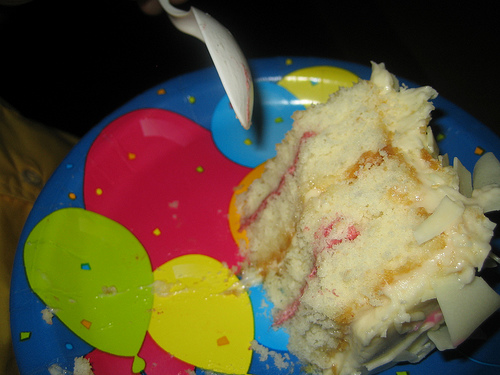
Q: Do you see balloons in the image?
A: Yes, there is a balloon.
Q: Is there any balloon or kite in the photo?
A: Yes, there is a balloon.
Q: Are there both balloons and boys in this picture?
A: No, there is a balloon but no boys.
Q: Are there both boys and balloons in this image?
A: No, there is a balloon but no boys.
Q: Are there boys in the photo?
A: No, there are no boys.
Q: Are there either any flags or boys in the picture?
A: No, there are no boys or flags.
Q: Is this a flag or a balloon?
A: This is a balloon.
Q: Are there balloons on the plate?
A: Yes, there is a balloon on the plate.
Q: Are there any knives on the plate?
A: No, there is a balloon on the plate.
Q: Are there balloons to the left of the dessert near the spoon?
A: Yes, there is a balloon to the left of the cake.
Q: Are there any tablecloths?
A: No, there are no tablecloths.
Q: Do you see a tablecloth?
A: No, there are no tablecloths.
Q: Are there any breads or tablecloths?
A: No, there are no tablecloths or breads.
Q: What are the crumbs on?
A: The crumbs are on the plate.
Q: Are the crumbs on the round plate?
A: Yes, the crumbs are on the plate.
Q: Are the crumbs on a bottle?
A: No, the crumbs are on the plate.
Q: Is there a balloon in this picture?
A: Yes, there is a balloon.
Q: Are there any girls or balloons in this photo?
A: Yes, there is a balloon.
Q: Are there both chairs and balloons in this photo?
A: No, there is a balloon but no chairs.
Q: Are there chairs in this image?
A: No, there are no chairs.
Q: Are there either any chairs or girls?
A: No, there are no chairs or girls.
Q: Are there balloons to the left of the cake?
A: Yes, there is a balloon to the left of the cake.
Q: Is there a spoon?
A: Yes, there is a spoon.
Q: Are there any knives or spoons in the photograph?
A: Yes, there is a spoon.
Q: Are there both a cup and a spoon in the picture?
A: No, there is a spoon but no cups.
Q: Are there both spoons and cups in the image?
A: No, there is a spoon but no cups.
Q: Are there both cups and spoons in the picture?
A: No, there is a spoon but no cups.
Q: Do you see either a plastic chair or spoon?
A: Yes, there is a plastic spoon.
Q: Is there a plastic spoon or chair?
A: Yes, there is a plastic spoon.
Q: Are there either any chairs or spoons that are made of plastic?
A: Yes, the spoon is made of plastic.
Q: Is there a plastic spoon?
A: Yes, there is a spoon that is made of plastic.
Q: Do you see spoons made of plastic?
A: Yes, there is a spoon that is made of plastic.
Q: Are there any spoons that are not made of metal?
A: Yes, there is a spoon that is made of plastic.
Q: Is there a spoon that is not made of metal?
A: Yes, there is a spoon that is made of plastic.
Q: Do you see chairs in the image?
A: No, there are no chairs.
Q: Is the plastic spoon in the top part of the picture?
A: Yes, the spoon is in the top of the image.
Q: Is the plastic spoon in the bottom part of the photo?
A: No, the spoon is in the top of the image.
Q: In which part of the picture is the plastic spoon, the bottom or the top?
A: The spoon is in the top of the image.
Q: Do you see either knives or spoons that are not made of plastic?
A: No, there is a spoon but it is made of plastic.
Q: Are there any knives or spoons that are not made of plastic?
A: No, there is a spoon but it is made of plastic.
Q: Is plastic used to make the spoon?
A: Yes, the spoon is made of plastic.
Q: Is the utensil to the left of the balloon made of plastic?
A: Yes, the spoon is made of plastic.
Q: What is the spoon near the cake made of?
A: The spoon is made of plastic.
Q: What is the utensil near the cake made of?
A: The spoon is made of plastic.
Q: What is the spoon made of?
A: The spoon is made of plastic.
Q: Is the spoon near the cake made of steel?
A: No, the spoon is made of plastic.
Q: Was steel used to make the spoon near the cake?
A: No, the spoon is made of plastic.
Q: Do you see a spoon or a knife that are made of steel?
A: No, there is a spoon but it is made of plastic.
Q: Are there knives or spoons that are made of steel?
A: No, there is a spoon but it is made of plastic.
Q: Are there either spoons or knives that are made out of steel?
A: No, there is a spoon but it is made of plastic.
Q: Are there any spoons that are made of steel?
A: No, there is a spoon but it is made of plastic.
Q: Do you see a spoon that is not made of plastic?
A: No, there is a spoon but it is made of plastic.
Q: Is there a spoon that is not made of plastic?
A: No, there is a spoon but it is made of plastic.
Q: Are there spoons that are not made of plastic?
A: No, there is a spoon but it is made of plastic.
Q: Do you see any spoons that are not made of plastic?
A: No, there is a spoon but it is made of plastic.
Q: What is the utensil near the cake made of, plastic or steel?
A: The spoon is made of plastic.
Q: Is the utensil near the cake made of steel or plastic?
A: The spoon is made of plastic.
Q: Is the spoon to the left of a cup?
A: No, the spoon is to the left of the balloon.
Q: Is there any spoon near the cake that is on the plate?
A: Yes, there is a spoon near the cake.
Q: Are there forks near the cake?
A: No, there is a spoon near the cake.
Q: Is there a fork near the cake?
A: No, there is a spoon near the cake.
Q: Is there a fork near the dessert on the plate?
A: No, there is a spoon near the cake.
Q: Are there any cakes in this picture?
A: Yes, there is a cake.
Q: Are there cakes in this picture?
A: Yes, there is a cake.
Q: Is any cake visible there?
A: Yes, there is a cake.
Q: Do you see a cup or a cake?
A: Yes, there is a cake.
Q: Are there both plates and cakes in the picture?
A: Yes, there are both a cake and a plate.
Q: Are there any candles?
A: No, there are no candles.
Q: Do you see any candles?
A: No, there are no candles.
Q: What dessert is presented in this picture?
A: The dessert is a cake.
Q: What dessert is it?
A: The dessert is a cake.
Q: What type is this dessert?
A: This is a cake.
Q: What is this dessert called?
A: This is a cake.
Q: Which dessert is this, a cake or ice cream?
A: This is a cake.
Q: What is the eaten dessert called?
A: The dessert is a cake.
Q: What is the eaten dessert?
A: The dessert is a cake.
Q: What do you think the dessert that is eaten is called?
A: The dessert is a cake.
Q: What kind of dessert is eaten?
A: The dessert is a cake.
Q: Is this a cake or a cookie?
A: This is a cake.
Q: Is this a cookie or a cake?
A: This is a cake.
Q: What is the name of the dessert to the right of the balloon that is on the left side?
A: The dessert is a cake.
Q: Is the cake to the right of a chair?
A: No, the cake is to the right of the balloon.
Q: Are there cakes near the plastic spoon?
A: Yes, there is a cake near the spoon.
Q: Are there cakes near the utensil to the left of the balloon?
A: Yes, there is a cake near the spoon.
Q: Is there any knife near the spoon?
A: No, there is a cake near the spoon.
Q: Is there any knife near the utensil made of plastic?
A: No, there is a cake near the spoon.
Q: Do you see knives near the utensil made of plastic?
A: No, there is a cake near the spoon.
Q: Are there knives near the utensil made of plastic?
A: No, there is a cake near the spoon.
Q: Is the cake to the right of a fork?
A: No, the cake is to the right of the balloon.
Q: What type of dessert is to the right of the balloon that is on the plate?
A: The dessert is a cake.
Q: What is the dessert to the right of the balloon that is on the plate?
A: The dessert is a cake.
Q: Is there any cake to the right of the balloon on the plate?
A: Yes, there is a cake to the right of the balloon.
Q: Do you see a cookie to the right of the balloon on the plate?
A: No, there is a cake to the right of the balloon.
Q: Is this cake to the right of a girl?
A: No, the cake is to the right of the balloon.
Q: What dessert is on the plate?
A: The dessert is a cake.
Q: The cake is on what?
A: The cake is on the plate.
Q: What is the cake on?
A: The cake is on the plate.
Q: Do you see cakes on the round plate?
A: Yes, there is a cake on the plate.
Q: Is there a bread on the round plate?
A: No, there is a cake on the plate.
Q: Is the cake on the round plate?
A: Yes, the cake is on the plate.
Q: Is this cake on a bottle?
A: No, the cake is on the plate.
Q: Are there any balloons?
A: Yes, there is a balloon.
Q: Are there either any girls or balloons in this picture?
A: Yes, there is a balloon.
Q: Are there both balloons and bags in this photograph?
A: No, there is a balloon but no bags.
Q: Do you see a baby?
A: No, there are no babies.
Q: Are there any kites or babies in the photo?
A: No, there are no babies or kites.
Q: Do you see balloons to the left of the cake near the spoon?
A: Yes, there is a balloon to the left of the cake.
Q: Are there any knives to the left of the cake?
A: No, there is a balloon to the left of the cake.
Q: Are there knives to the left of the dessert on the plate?
A: No, there is a balloon to the left of the cake.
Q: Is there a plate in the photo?
A: Yes, there is a plate.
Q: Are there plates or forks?
A: Yes, there is a plate.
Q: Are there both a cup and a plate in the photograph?
A: No, there is a plate but no cups.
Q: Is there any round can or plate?
A: Yes, there is a round plate.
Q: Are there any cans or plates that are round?
A: Yes, the plate is round.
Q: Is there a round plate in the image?
A: Yes, there is a round plate.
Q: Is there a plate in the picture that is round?
A: Yes, there is a plate that is round.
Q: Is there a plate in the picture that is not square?
A: Yes, there is a round plate.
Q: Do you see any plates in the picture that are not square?
A: Yes, there is a round plate.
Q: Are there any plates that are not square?
A: Yes, there is a round plate.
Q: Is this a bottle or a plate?
A: This is a plate.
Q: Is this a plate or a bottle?
A: This is a plate.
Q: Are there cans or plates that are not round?
A: No, there is a plate but it is round.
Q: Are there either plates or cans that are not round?
A: No, there is a plate but it is round.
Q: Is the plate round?
A: Yes, the plate is round.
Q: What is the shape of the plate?
A: The plate is round.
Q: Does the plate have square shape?
A: No, the plate is round.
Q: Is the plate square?
A: No, the plate is round.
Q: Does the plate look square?
A: No, the plate is round.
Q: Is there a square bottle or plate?
A: No, there is a plate but it is round.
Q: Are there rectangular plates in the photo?
A: No, there is a plate but it is round.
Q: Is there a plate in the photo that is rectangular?
A: No, there is a plate but it is round.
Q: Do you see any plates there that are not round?
A: No, there is a plate but it is round.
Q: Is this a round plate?
A: Yes, this is a round plate.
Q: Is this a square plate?
A: No, this is a round plate.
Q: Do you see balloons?
A: Yes, there is a balloon.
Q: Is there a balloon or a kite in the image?
A: Yes, there is a balloon.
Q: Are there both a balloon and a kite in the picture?
A: No, there is a balloon but no kites.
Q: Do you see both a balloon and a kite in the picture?
A: No, there is a balloon but no kites.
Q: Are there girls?
A: No, there are no girls.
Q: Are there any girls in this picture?
A: No, there are no girls.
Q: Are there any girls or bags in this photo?
A: No, there are no girls or bags.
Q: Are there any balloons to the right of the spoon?
A: Yes, there is a balloon to the right of the spoon.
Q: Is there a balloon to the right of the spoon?
A: Yes, there is a balloon to the right of the spoon.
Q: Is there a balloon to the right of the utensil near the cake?
A: Yes, there is a balloon to the right of the spoon.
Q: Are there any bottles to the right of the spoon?
A: No, there is a balloon to the right of the spoon.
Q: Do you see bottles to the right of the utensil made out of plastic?
A: No, there is a balloon to the right of the spoon.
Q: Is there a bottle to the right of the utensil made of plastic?
A: No, there is a balloon to the right of the spoon.